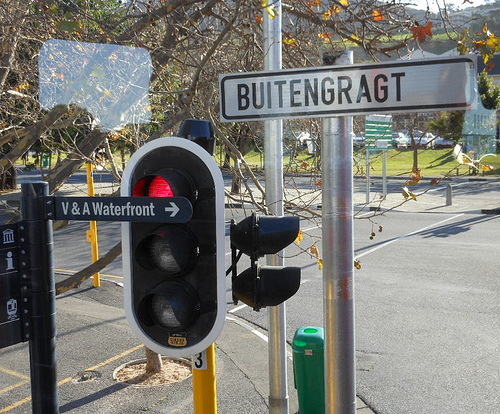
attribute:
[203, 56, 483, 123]
sign — black, white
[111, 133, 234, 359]
stop light — red, on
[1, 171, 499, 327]
road — black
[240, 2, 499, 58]
leaves — orange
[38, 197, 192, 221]
sign — white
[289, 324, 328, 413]
trash can — green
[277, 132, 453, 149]
cars — parked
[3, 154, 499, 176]
grass — green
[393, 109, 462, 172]
tree — brown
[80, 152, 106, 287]
pole — skinny, yellow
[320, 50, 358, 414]
pole — metal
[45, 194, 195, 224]
street sign — black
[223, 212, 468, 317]
line — white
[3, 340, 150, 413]
line — yellow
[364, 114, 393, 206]
sign — green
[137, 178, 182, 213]
light — red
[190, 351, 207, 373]
number — black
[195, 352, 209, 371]
sticker — white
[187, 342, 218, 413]
pole — yellow